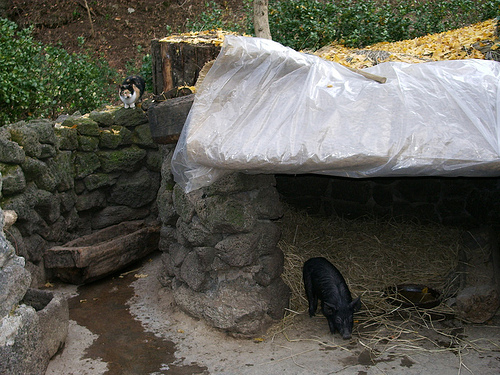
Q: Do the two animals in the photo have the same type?
A: No, they are pigs and cats.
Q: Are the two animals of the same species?
A: No, they are pigs and cats.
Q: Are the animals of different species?
A: Yes, they are pigs and cats.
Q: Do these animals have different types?
A: Yes, they are pigs and cats.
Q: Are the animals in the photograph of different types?
A: Yes, they are pigs and cats.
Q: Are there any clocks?
A: No, there are no clocks.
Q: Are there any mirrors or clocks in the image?
A: No, there are no clocks or mirrors.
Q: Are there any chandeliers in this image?
A: No, there are no chandeliers.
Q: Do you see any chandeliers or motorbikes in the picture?
A: No, there are no chandeliers or motorbikes.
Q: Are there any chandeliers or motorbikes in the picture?
A: No, there are no chandeliers or motorbikes.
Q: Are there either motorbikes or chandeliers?
A: No, there are no chandeliers or motorbikes.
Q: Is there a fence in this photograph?
A: No, there are no fences.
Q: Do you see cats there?
A: Yes, there is a cat.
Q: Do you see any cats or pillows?
A: Yes, there is a cat.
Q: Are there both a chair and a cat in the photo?
A: No, there is a cat but no chairs.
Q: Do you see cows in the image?
A: No, there are no cows.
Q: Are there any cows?
A: No, there are no cows.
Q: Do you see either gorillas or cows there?
A: No, there are no cows or gorillas.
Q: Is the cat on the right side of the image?
A: No, the cat is on the left of the image.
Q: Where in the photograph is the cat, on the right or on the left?
A: The cat is on the left of the image.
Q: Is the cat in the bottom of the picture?
A: No, the cat is in the top of the image.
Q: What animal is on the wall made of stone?
A: The cat is on the wall.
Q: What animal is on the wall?
A: The cat is on the wall.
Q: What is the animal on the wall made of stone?
A: The animal is a cat.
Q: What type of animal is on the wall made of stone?
A: The animal is a cat.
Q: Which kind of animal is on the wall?
A: The animal is a cat.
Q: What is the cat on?
A: The cat is on the wall.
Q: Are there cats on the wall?
A: Yes, there is a cat on the wall.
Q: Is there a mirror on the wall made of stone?
A: No, there is a cat on the wall.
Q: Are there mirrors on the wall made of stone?
A: No, there is a cat on the wall.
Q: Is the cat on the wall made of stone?
A: Yes, the cat is on the wall.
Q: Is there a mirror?
A: No, there are no mirrors.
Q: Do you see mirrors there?
A: No, there are no mirrors.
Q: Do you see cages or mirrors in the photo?
A: No, there are no mirrors or cages.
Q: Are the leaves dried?
A: Yes, the leaves are dried.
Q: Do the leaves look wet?
A: No, the leaves are dried.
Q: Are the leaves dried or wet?
A: The leaves are dried.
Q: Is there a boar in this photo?
A: Yes, there is a boar.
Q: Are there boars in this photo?
A: Yes, there is a boar.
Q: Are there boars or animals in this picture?
A: Yes, there is a boar.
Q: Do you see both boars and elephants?
A: No, there is a boar but no elephants.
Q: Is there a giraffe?
A: No, there are no giraffes.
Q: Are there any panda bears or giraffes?
A: No, there are no giraffes or panda bears.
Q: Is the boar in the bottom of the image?
A: Yes, the boar is in the bottom of the image.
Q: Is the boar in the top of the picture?
A: No, the boar is in the bottom of the image.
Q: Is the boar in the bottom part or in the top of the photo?
A: The boar is in the bottom of the image.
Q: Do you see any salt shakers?
A: No, there are no salt shakers.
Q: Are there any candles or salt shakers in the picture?
A: No, there are no salt shakers or candles.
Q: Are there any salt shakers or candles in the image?
A: No, there are no salt shakers or candles.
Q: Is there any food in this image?
A: Yes, there is food.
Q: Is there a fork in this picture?
A: No, there are no forks.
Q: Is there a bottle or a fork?
A: No, there are no forks or bottles.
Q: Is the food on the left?
A: Yes, the food is on the left of the image.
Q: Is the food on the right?
A: No, the food is on the left of the image.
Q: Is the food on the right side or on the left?
A: The food is on the left of the image.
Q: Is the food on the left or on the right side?
A: The food is on the left of the image.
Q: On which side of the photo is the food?
A: The food is on the left of the image.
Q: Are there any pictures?
A: No, there are no pictures.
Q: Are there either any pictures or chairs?
A: No, there are no pictures or chairs.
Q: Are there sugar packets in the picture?
A: No, there are no sugar packets.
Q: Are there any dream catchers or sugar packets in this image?
A: No, there are no sugar packets or dream catchers.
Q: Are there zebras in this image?
A: No, there are no zebras.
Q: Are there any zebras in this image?
A: No, there are no zebras.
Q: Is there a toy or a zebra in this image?
A: No, there are no zebras or toys.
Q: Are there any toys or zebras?
A: No, there are no zebras or toys.